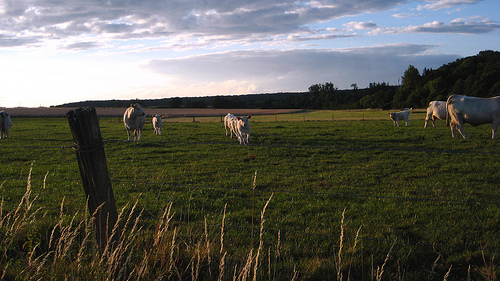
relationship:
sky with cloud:
[1, 0, 499, 107] [373, 19, 495, 37]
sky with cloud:
[1, 0, 499, 107] [0, 2, 399, 39]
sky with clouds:
[1, 0, 499, 107] [137, 41, 468, 95]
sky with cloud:
[1, 0, 499, 107] [415, 1, 477, 13]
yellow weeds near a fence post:
[21, 200, 442, 280] [65, 104, 130, 280]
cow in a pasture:
[112, 99, 147, 139] [1, 107, 499, 278]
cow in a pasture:
[149, 107, 166, 132] [1, 107, 499, 278]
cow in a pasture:
[233, 110, 257, 147] [1, 107, 499, 278]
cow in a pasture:
[441, 89, 498, 140] [1, 107, 499, 278]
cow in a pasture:
[418, 95, 449, 129] [1, 107, 499, 278]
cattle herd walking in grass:
[118, 91, 498, 145] [5, 112, 498, 279]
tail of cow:
[444, 91, 458, 128] [151, 113, 164, 136]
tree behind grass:
[305, 80, 342, 108] [5, 112, 498, 279]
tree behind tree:
[392, 62, 426, 102] [305, 80, 342, 108]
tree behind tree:
[408, 72, 454, 104] [305, 80, 342, 108]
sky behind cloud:
[358, 39, 480, 47] [248, 7, 445, 80]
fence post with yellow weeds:
[66, 102, 121, 256] [0, 158, 500, 281]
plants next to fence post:
[11, 155, 498, 279] [72, 97, 130, 247]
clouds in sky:
[0, 0, 498, 107] [1, 0, 499, 107]